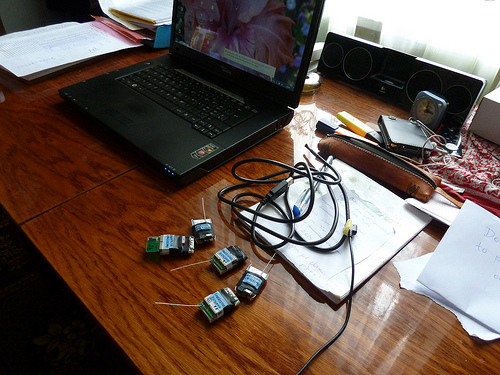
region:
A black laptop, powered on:
[56, 1, 328, 187]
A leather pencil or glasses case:
[318, 126, 443, 206]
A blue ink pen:
[290, 153, 332, 220]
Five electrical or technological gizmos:
[132, 191, 284, 321]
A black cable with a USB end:
[214, 138, 366, 370]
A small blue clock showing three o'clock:
[414, 89, 446, 128]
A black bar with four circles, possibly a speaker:
[317, 28, 485, 130]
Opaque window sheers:
[307, 0, 499, 73]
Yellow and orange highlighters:
[316, 106, 385, 147]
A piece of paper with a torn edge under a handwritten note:
[387, 249, 499, 348]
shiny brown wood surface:
[171, 331, 269, 365]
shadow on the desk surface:
[359, 305, 436, 349]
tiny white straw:
[146, 294, 203, 315]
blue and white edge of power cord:
[336, 217, 367, 235]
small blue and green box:
[181, 279, 242, 325]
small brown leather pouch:
[321, 128, 456, 193]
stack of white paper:
[250, 158, 407, 325]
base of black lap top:
[72, 53, 280, 191]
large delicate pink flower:
[196, 11, 295, 53]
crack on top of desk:
[53, 170, 127, 201]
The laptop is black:
[57, 2, 331, 189]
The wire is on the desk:
[227, 139, 360, 373]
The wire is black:
[220, 137, 360, 370]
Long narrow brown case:
[319, 127, 436, 203]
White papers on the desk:
[228, 165, 496, 343]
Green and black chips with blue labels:
[144, 201, 277, 325]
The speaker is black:
[315, 23, 482, 133]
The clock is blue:
[410, 84, 450, 131]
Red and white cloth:
[427, 129, 497, 211]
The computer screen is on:
[53, 0, 321, 198]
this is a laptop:
[116, 5, 284, 137]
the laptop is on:
[190, 4, 274, 71]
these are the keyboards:
[166, 80, 206, 110]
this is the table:
[33, 151, 114, 227]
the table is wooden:
[13, 143, 112, 219]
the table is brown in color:
[20, 150, 125, 225]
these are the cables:
[225, 159, 342, 238]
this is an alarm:
[410, 92, 447, 119]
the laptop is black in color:
[141, 120, 182, 156]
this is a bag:
[387, 156, 422, 184]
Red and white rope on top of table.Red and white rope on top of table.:
[213, 241, 231, 272]